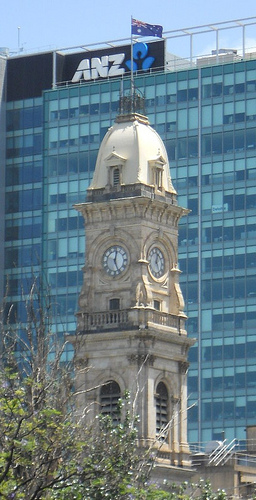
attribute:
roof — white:
[41, 50, 255, 87]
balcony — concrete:
[69, 298, 194, 336]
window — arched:
[154, 378, 173, 443]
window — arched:
[97, 379, 121, 435]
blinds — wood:
[97, 375, 170, 443]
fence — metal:
[178, 438, 255, 466]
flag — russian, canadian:
[111, 14, 198, 106]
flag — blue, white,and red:
[122, 16, 167, 42]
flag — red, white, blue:
[122, 14, 164, 124]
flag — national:
[129, 13, 163, 117]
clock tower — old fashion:
[69, 133, 226, 461]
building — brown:
[79, 74, 192, 447]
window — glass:
[212, 276, 223, 308]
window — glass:
[221, 305, 235, 336]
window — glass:
[222, 100, 236, 130]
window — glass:
[221, 128, 233, 158]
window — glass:
[187, 134, 199, 162]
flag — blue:
[129, 17, 167, 40]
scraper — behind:
[2, 1, 253, 449]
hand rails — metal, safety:
[203, 436, 243, 467]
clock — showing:
[82, 227, 149, 294]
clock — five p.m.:
[95, 240, 131, 280]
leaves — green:
[3, 368, 84, 498]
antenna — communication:
[118, 75, 124, 106]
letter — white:
[70, 56, 91, 82]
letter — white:
[91, 53, 111, 79]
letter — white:
[107, 50, 126, 76]